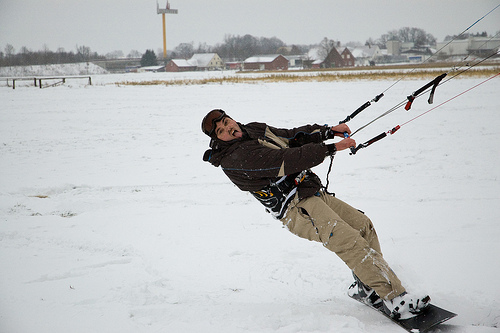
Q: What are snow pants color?
A: Beige.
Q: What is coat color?
A: Brown.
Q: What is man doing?
A: Leaning.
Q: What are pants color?
A: Tan.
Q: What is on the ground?
A: Snow.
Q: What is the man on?
A: Snowboard.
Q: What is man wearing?
A: Pants.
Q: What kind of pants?
A: Snow.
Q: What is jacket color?
A: Brown.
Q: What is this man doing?
A: Snowboarding.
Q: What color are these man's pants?
A: Khaki.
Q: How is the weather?
A: Cold and clear.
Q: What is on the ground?
A: Snow.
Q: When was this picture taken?
A: Daytime.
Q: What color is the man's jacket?
A: Black.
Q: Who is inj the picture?
A: A man.